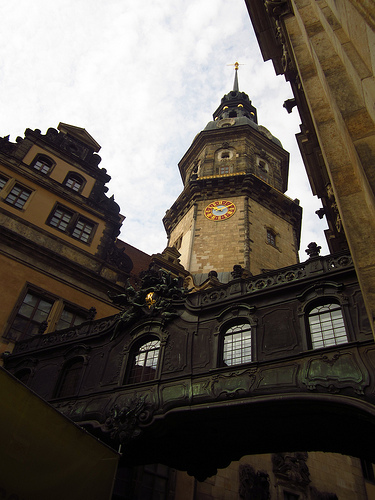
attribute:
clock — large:
[200, 197, 236, 222]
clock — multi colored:
[195, 200, 230, 227]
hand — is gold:
[212, 199, 235, 215]